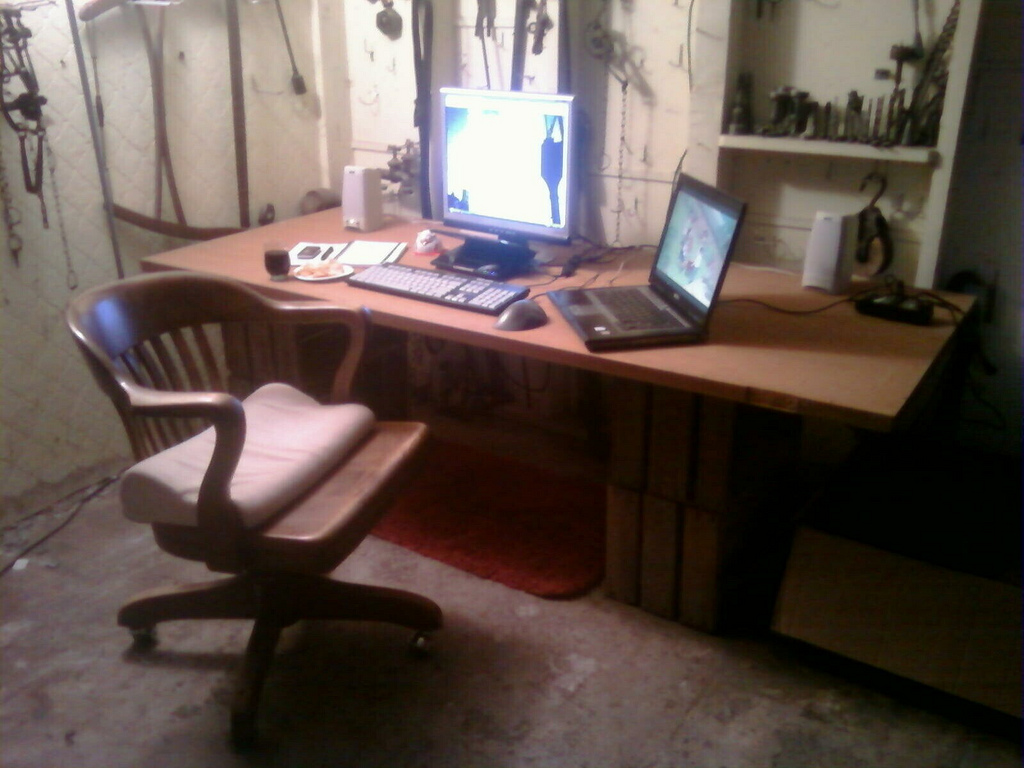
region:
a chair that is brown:
[70, 268, 444, 703]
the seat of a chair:
[222, 429, 423, 560]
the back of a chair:
[55, 294, 286, 451]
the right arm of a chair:
[122, 367, 262, 513]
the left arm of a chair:
[245, 294, 382, 387]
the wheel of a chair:
[119, 610, 151, 653]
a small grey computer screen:
[397, 83, 604, 232]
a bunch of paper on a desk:
[263, 239, 391, 285]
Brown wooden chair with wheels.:
[64, 271, 451, 743]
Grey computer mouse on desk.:
[490, 293, 554, 335]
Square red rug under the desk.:
[367, 424, 615, 603]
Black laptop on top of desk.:
[550, 174, 750, 353]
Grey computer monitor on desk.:
[419, 88, 585, 251]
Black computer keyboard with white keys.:
[340, 255, 527, 316]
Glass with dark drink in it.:
[257, 234, 292, 277]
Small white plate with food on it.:
[294, 258, 355, 285]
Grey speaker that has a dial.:
[327, 164, 384, 235]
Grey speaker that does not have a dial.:
[798, 203, 856, 302]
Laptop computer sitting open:
[542, 166, 743, 348]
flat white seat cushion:
[115, 380, 376, 533]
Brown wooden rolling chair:
[54, 264, 440, 708]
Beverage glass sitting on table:
[257, 235, 287, 274]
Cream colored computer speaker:
[800, 203, 835, 286]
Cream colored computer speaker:
[337, 159, 382, 229]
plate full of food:
[295, 256, 352, 283]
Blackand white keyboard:
[348, 250, 526, 315]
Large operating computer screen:
[428, 78, 581, 244]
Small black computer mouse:
[498, 295, 547, 335]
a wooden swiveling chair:
[62, 270, 443, 752]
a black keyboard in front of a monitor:
[349, 261, 531, 325]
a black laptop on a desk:
[539, 170, 749, 352]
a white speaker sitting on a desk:
[800, 210, 843, 294]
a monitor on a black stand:
[433, 87, 576, 283]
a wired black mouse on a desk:
[500, 299, 546, 329]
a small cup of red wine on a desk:
[260, 248, 290, 283]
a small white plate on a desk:
[292, 261, 350, 285]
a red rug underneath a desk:
[374, 435, 605, 600]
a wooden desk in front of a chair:
[143, 205, 973, 639]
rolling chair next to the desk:
[72, 251, 449, 730]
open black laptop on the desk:
[552, 165, 749, 362]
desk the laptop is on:
[174, 177, 978, 653]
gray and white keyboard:
[344, 262, 522, 329]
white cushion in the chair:
[142, 371, 364, 511]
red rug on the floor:
[337, 420, 607, 610]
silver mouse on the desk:
[490, 292, 538, 337]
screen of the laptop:
[650, 191, 736, 299]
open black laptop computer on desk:
[545, 169, 745, 353]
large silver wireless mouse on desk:
[497, 298, 549, 333]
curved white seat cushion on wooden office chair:
[124, 377, 375, 518]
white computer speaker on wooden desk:
[339, 166, 379, 230]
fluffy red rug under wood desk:
[371, 437, 613, 603]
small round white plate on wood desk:
[291, 260, 350, 281]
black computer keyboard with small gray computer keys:
[346, 260, 530, 317]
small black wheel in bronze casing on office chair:
[411, 636, 430, 655]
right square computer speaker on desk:
[795, 207, 857, 296]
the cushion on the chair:
[65, 268, 446, 744]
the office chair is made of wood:
[62, 269, 445, 750]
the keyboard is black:
[348, 260, 532, 311]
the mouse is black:
[494, 298, 551, 334]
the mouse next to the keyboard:
[348, 260, 551, 333]